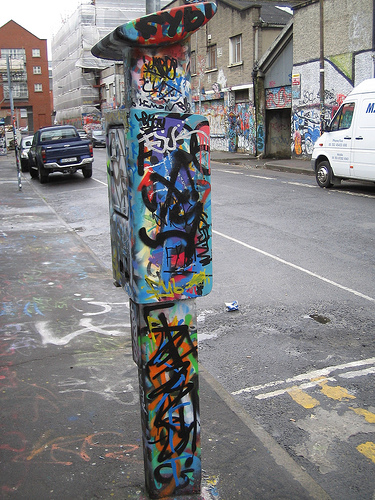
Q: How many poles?
A: 2.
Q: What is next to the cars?
A: Buildings.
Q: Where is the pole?
A: Next to the street.